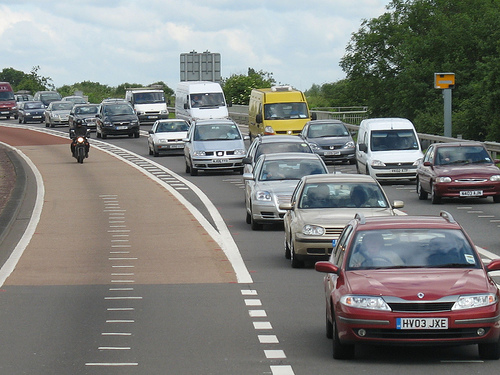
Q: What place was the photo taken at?
A: It was taken at the road.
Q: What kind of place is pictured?
A: It is a road.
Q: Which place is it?
A: It is a road.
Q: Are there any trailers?
A: No, there are no trailers.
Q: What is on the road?
A: The car is on the road.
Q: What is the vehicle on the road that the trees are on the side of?
A: The vehicle is a car.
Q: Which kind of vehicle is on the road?
A: The vehicle is a car.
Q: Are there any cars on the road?
A: Yes, there is a car on the road.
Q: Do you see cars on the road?
A: Yes, there is a car on the road.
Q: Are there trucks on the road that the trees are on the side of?
A: No, there is a car on the road.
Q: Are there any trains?
A: No, there are no trains.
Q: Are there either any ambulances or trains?
A: No, there are no trains or ambulances.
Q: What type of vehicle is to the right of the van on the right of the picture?
A: The vehicle is a car.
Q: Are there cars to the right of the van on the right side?
A: Yes, there is a car to the right of the van.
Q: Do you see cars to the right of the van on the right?
A: Yes, there is a car to the right of the van.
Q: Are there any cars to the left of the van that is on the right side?
A: No, the car is to the right of the van.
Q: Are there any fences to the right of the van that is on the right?
A: No, there is a car to the right of the van.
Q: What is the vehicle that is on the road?
A: The vehicle is a car.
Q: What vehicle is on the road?
A: The vehicle is a car.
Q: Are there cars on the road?
A: Yes, there is a car on the road.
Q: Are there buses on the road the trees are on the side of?
A: No, there is a car on the road.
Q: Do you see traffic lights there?
A: No, there are no traffic lights.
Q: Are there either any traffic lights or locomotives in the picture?
A: No, there are no traffic lights or locomotives.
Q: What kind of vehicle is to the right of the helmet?
A: The vehicle is a van.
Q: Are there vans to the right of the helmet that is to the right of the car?
A: Yes, there is a van to the right of the helmet.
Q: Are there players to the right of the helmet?
A: No, there is a van to the right of the helmet.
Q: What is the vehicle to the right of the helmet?
A: The vehicle is a van.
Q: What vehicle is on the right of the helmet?
A: The vehicle is a van.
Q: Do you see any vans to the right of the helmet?
A: Yes, there is a van to the right of the helmet.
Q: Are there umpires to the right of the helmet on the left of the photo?
A: No, there is a van to the right of the helmet.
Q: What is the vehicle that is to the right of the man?
A: The vehicle is a van.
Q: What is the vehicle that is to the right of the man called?
A: The vehicle is a van.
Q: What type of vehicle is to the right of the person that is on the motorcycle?
A: The vehicle is a van.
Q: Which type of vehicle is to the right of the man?
A: The vehicle is a van.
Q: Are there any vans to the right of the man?
A: Yes, there is a van to the right of the man.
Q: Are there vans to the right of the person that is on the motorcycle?
A: Yes, there is a van to the right of the man.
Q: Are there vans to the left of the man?
A: No, the van is to the right of the man.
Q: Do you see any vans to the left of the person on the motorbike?
A: No, the van is to the right of the man.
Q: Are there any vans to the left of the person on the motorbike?
A: No, the van is to the right of the man.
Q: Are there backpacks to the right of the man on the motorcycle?
A: No, there is a van to the right of the man.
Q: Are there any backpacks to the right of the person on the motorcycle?
A: No, there is a van to the right of the man.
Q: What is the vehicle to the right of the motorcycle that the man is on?
A: The vehicle is a van.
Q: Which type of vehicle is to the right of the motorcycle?
A: The vehicle is a van.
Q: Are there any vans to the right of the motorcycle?
A: Yes, there is a van to the right of the motorcycle.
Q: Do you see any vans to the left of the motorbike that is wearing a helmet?
A: No, the van is to the right of the motorbike.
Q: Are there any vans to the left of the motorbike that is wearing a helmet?
A: No, the van is to the right of the motorbike.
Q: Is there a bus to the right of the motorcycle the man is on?
A: No, there is a van to the right of the motorcycle.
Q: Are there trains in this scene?
A: No, there are no trains.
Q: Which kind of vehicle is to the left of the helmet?
A: The vehicle is a car.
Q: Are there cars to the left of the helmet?
A: Yes, there is a car to the left of the helmet.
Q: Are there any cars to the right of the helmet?
A: No, the car is to the left of the helmet.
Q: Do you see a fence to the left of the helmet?
A: No, there is a car to the left of the helmet.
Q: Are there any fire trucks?
A: No, there are no fire trucks.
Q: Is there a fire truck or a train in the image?
A: No, there are no fire trucks or trains.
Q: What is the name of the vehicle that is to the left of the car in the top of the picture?
A: The vehicle is a van.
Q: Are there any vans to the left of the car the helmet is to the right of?
A: Yes, there is a van to the left of the car.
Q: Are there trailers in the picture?
A: No, there are no trailers.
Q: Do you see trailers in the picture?
A: No, there are no trailers.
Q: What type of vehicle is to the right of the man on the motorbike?
A: The vehicle is a van.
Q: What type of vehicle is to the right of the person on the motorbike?
A: The vehicle is a van.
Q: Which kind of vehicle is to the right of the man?
A: The vehicle is a van.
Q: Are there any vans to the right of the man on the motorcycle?
A: Yes, there is a van to the right of the man.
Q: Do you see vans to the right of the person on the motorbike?
A: Yes, there is a van to the right of the man.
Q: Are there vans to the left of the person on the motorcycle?
A: No, the van is to the right of the man.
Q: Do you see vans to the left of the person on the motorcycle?
A: No, the van is to the right of the man.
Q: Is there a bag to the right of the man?
A: No, there is a van to the right of the man.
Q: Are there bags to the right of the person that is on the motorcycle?
A: No, there is a van to the right of the man.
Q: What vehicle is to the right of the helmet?
A: The vehicle is a van.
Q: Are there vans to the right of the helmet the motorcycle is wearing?
A: Yes, there is a van to the right of the helmet.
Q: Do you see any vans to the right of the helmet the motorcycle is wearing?
A: Yes, there is a van to the right of the helmet.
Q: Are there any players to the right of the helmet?
A: No, there is a van to the right of the helmet.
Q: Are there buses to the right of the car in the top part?
A: No, there is a van to the right of the car.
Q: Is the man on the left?
A: Yes, the man is on the left of the image.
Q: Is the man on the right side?
A: No, the man is on the left of the image.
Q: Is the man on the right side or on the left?
A: The man is on the left of the image.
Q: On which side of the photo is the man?
A: The man is on the left of the image.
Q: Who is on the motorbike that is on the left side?
A: The man is on the motorbike.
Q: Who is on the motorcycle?
A: The man is on the motorbike.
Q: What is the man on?
A: The man is on the motorcycle.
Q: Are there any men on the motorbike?
A: Yes, there is a man on the motorbike.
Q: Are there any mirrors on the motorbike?
A: No, there is a man on the motorbike.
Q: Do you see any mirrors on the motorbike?
A: No, there is a man on the motorbike.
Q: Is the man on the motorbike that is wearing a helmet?
A: Yes, the man is on the motorbike.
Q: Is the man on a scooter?
A: No, the man is on the motorbike.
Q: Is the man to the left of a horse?
A: No, the man is to the left of the van.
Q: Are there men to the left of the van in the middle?
A: Yes, there is a man to the left of the van.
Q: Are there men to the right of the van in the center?
A: No, the man is to the left of the van.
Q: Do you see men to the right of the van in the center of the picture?
A: No, the man is to the left of the van.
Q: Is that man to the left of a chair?
A: No, the man is to the left of the van.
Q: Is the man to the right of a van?
A: No, the man is to the left of a van.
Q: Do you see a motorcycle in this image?
A: Yes, there is a motorcycle.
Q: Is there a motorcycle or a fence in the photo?
A: Yes, there is a motorcycle.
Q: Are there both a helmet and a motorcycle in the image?
A: Yes, there are both a motorcycle and a helmet.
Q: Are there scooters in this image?
A: No, there are no scooters.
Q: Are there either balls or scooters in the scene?
A: No, there are no scooters or balls.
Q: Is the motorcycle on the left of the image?
A: Yes, the motorcycle is on the left of the image.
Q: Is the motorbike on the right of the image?
A: No, the motorbike is on the left of the image.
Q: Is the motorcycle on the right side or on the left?
A: The motorcycle is on the left of the image.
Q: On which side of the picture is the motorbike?
A: The motorbike is on the left of the image.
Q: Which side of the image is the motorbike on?
A: The motorbike is on the left of the image.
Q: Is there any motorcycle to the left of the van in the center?
A: Yes, there is a motorcycle to the left of the van.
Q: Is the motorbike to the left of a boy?
A: No, the motorbike is to the left of the van.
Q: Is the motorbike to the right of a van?
A: No, the motorbike is to the left of a van.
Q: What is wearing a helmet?
A: The motorbike is wearing a helmet.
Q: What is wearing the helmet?
A: The motorbike is wearing a helmet.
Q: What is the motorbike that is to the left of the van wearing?
A: The motorcycle is wearing a helmet.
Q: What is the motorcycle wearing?
A: The motorcycle is wearing a helmet.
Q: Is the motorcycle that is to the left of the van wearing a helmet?
A: Yes, the motorcycle is wearing a helmet.